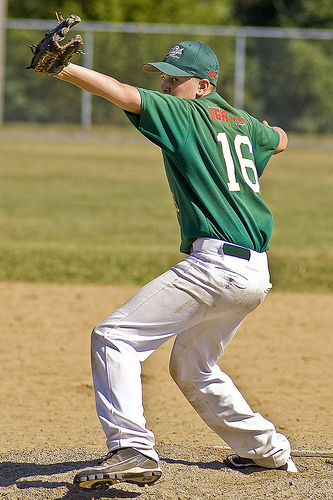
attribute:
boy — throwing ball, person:
[27, 10, 296, 492]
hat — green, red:
[142, 40, 219, 89]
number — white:
[213, 130, 260, 194]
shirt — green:
[126, 86, 281, 254]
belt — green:
[220, 243, 253, 261]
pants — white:
[88, 237, 291, 471]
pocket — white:
[209, 266, 246, 308]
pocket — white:
[255, 282, 271, 307]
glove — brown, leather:
[27, 10, 86, 79]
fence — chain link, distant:
[2, 17, 332, 152]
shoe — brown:
[71, 446, 162, 492]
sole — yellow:
[76, 469, 161, 491]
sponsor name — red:
[209, 105, 247, 129]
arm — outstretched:
[54, 63, 142, 114]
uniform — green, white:
[89, 86, 291, 468]